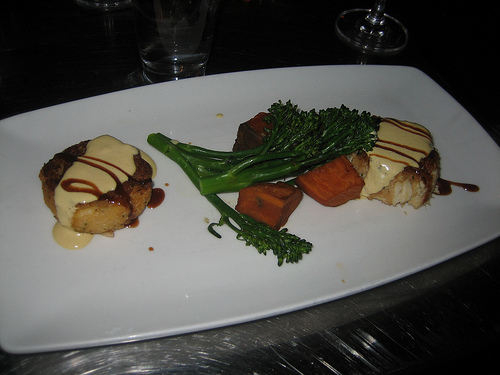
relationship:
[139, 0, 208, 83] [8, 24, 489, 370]
glass on top of table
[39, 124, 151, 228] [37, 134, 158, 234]
sauce on top of food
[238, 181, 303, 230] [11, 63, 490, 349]
potato on top of plate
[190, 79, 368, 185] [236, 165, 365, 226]
broccoli on top of potatoes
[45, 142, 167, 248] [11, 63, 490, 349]
food on top of plate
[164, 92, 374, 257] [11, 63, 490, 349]
vegetable on top of plate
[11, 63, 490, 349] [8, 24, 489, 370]
plate on table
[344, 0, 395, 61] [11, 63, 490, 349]
glass by plate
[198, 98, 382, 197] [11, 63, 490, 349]
vegetable on plate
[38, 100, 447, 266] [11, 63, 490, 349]
dinner on plate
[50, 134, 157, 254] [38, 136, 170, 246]
sauce on meat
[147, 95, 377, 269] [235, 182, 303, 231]
broccoli on top of potato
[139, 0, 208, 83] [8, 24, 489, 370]
glass on table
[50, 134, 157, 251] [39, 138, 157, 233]
sauce drizzled on meat